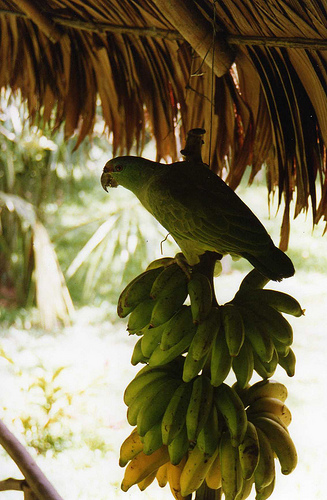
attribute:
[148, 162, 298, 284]
feathers — green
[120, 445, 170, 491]
banana — yellow 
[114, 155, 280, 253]
bird — green, tropical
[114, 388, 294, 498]
bananas — yellow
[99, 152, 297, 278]
bird — green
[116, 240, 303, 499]
bananas — hanging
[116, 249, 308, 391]
bananas — green, yellow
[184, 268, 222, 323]
banana — unrippen, green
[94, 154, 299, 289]
macaw — green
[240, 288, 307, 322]
banana — green 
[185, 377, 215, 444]
banana — green 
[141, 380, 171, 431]
banana — green 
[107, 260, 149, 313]
banana — green 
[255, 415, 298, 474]
banana — green 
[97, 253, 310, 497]
bananas — green 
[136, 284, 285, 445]
bananas — green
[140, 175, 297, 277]
feathers — green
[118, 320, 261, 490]
bananas — yellow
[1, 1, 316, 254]
hut — grass